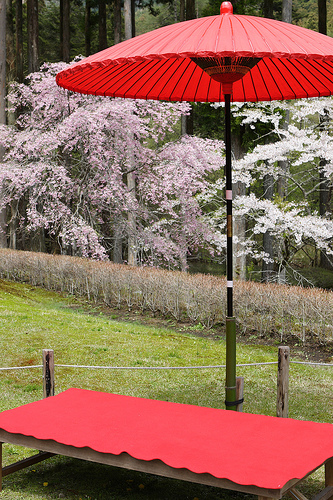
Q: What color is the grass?
A: Green.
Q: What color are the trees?
A: White.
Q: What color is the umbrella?
A: Red.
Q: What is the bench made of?
A: Wood.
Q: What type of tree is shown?
A: Cherry blossom.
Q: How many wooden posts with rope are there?
A: Two.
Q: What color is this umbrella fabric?
A: Red.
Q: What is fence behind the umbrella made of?
A: Wood and rope.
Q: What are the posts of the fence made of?
A: Wood.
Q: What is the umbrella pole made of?
A: Metal.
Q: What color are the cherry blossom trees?
A: Pink.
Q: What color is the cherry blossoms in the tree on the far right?
A: White.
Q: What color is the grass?
A: Green.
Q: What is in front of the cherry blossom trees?
A: A row of dying shrubbery.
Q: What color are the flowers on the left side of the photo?
A: Pink.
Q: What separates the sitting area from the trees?
A: A lining of bushes near the edge of the grass.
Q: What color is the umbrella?
A: Red.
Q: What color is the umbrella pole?
A: Black.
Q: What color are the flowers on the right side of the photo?
A: White.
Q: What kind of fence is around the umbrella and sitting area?
A: A rope and wood fence.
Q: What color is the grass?
A: Green.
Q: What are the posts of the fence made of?
A: Wood.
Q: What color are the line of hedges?
A: Brown.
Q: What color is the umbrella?
A: Red.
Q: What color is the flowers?
A: Pink.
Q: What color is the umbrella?
A: Red.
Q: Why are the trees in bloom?
A: Springtime.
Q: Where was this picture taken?
A: Lawn.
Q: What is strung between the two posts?
A: Rope.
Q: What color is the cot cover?
A: Red.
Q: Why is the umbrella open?
A: Shade.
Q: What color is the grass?
A: Green.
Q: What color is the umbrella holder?
A: Green.